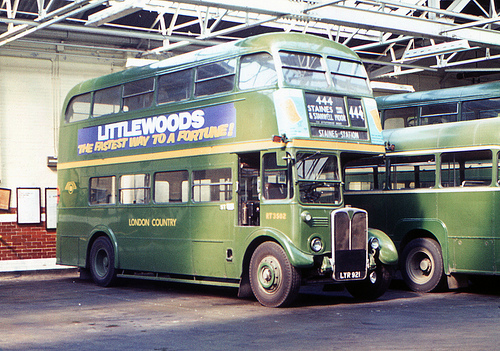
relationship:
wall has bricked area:
[1, 52, 122, 259] [2, 220, 56, 259]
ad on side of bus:
[73, 100, 239, 159] [51, 30, 403, 308]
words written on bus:
[119, 209, 191, 231] [51, 30, 403, 308]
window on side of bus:
[232, 149, 263, 226] [51, 30, 403, 308]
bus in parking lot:
[51, 30, 403, 308] [3, 265, 497, 349]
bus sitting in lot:
[51, 30, 403, 308] [0, 264, 499, 349]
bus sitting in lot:
[338, 118, 499, 296] [0, 264, 499, 349]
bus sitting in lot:
[367, 71, 499, 136] [0, 264, 499, 349]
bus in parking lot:
[47, 47, 403, 308] [7, 227, 497, 337]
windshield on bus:
[294, 152, 344, 203] [51, 30, 403, 308]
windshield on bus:
[294, 152, 344, 203] [347, 111, 499, 287]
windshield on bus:
[294, 152, 344, 203] [372, 80, 499, 128]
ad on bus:
[75, 100, 239, 155] [51, 30, 403, 308]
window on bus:
[194, 54, 237, 81] [51, 30, 403, 308]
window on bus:
[195, 74, 232, 97] [51, 30, 403, 308]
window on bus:
[157, 65, 189, 103] [51, 30, 403, 308]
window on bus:
[122, 73, 154, 97] [51, 30, 403, 308]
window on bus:
[124, 91, 151, 113] [51, 30, 403, 308]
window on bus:
[92, 83, 123, 118] [51, 30, 403, 308]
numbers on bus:
[336, 270, 368, 283] [51, 30, 403, 308]